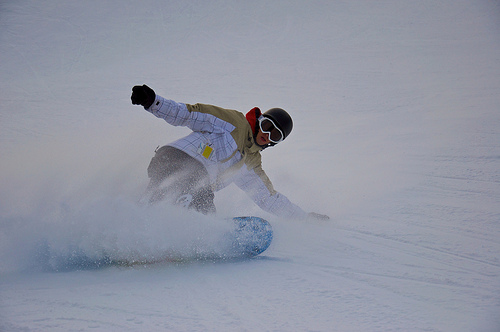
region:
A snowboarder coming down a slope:
[107, 65, 362, 273]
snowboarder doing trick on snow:
[105, 74, 333, 271]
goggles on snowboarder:
[250, 110, 282, 143]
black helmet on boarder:
[261, 92, 316, 137]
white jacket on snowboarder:
[146, 88, 317, 223]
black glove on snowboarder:
[128, 66, 167, 117]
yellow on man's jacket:
[184, 94, 274, 160]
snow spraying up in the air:
[21, 154, 151, 277]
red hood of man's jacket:
[239, 101, 258, 134]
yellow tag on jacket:
[192, 141, 224, 166]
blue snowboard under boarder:
[89, 194, 294, 265]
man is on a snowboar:
[136, 78, 328, 260]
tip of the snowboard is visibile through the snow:
[227, 218, 281, 264]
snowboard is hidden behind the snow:
[46, 206, 241, 264]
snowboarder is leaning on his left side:
[125, 68, 337, 265]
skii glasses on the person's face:
[251, 113, 284, 145]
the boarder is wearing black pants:
[142, 149, 215, 211]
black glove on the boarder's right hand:
[125, 85, 159, 114]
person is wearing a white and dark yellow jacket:
[153, 91, 304, 228]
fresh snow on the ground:
[0, 79, 494, 327]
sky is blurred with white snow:
[1, 3, 495, 136]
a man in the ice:
[76, 50, 458, 311]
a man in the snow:
[31, 34, 346, 301]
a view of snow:
[278, 219, 452, 329]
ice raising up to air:
[12, 180, 345, 299]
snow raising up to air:
[18, 175, 265, 267]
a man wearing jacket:
[145, 74, 265, 199]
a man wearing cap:
[240, 74, 328, 179]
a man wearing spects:
[250, 102, 306, 177]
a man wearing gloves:
[127, 65, 183, 137]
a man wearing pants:
[121, 125, 224, 220]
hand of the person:
[253, 180, 333, 228]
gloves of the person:
[122, 73, 159, 126]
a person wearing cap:
[224, 79, 295, 154]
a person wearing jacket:
[154, 87, 279, 217]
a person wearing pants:
[141, 145, 238, 217]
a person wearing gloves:
[114, 58, 182, 146]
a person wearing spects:
[253, 90, 319, 152]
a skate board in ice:
[38, 175, 344, 290]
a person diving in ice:
[37, 23, 419, 328]